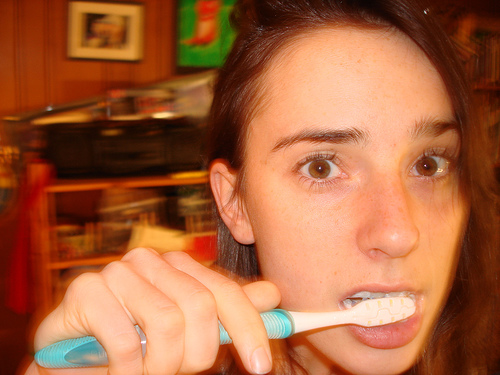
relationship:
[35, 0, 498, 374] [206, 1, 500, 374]
woman with hair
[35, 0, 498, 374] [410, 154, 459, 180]
woman with left eye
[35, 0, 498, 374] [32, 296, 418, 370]
woman holding toothbrush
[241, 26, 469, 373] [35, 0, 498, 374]
head of woman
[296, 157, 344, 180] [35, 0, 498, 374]
eye of woman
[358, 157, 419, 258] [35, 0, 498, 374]
nose of woman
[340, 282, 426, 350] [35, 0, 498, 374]
mouth of woman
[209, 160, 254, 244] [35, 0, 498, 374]
right ear of woman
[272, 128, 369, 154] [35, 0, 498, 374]
eyebrow of woman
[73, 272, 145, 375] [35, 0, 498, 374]
finger of woman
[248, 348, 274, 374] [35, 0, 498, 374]
fingernail of woman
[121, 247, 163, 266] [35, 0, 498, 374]
knuckle of woman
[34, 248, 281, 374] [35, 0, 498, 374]
hand of woman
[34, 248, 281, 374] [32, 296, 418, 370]
hand holding toothbrush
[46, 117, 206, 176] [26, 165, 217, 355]
radio on cabinet